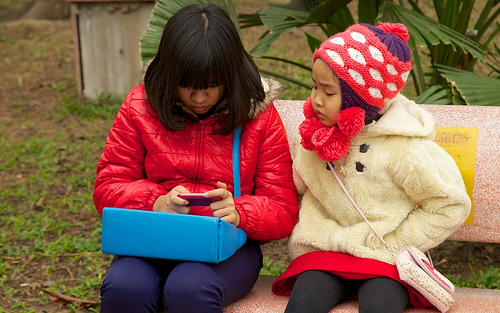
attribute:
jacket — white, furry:
[285, 92, 472, 267]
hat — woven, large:
[298, 19, 414, 159]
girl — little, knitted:
[271, 23, 471, 312]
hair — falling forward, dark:
[144, 5, 264, 135]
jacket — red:
[95, 82, 299, 240]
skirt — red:
[269, 252, 427, 312]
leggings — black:
[283, 269, 409, 311]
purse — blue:
[101, 128, 248, 262]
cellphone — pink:
[178, 190, 217, 203]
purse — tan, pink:
[325, 161, 457, 311]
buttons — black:
[312, 138, 372, 178]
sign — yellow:
[421, 117, 483, 235]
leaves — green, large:
[395, 1, 474, 53]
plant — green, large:
[132, 1, 484, 105]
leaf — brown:
[42, 280, 114, 310]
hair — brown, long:
[133, 1, 292, 141]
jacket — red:
[65, 55, 303, 254]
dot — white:
[337, 45, 365, 66]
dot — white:
[359, 58, 388, 88]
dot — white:
[344, 28, 370, 44]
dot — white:
[397, 69, 413, 88]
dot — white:
[323, 30, 349, 50]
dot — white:
[342, 38, 372, 65]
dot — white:
[360, 61, 390, 83]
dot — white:
[382, 80, 402, 93]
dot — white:
[313, 45, 345, 69]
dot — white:
[335, 66, 377, 91]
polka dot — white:
[324, 44, 346, 68]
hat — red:
[306, 18, 415, 132]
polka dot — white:
[344, 42, 371, 66]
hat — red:
[308, 19, 416, 112]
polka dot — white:
[365, 61, 389, 85]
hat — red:
[309, 18, 416, 124]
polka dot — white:
[365, 85, 386, 103]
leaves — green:
[411, 16, 441, 68]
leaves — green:
[394, 3, 498, 69]